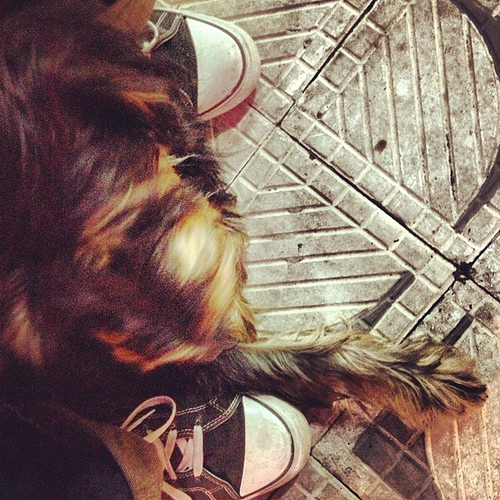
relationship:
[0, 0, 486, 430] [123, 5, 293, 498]
dog sitting between feet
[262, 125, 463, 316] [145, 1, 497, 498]
ornate tile sitting covering floor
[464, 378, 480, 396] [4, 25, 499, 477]
toenail on dog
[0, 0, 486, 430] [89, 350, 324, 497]
dog laying between shoe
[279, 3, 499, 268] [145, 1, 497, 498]
tile on floor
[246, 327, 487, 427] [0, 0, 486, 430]
paw on dog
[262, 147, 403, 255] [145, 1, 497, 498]
dirt on floor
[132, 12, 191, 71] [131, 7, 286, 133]
lace on shoe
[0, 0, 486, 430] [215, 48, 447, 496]
dog on ground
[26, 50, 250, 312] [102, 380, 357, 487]
person wearing shoe